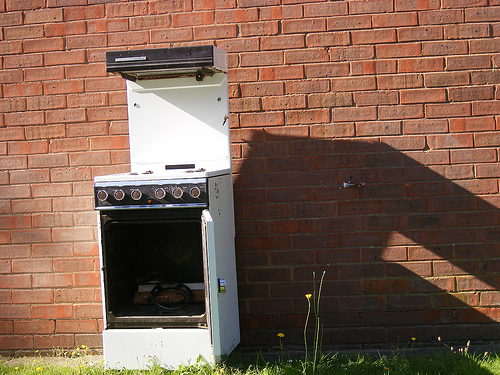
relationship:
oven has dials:
[93, 43, 246, 371] [89, 175, 215, 206]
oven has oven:
[93, 43, 246, 371] [93, 44, 245, 371]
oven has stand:
[93, 43, 246, 371] [107, 41, 231, 105]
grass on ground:
[3, 354, 499, 374] [3, 343, 497, 372]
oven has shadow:
[93, 43, 246, 371] [233, 122, 498, 348]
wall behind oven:
[2, 3, 495, 350] [93, 43, 246, 371]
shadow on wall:
[233, 122, 498, 348] [2, 3, 495, 350]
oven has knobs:
[93, 43, 246, 371] [89, 175, 215, 206]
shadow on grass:
[233, 122, 498, 348] [3, 354, 499, 374]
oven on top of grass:
[93, 43, 246, 371] [3, 354, 499, 374]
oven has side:
[93, 43, 246, 371] [203, 173, 247, 359]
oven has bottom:
[93, 43, 246, 371] [101, 328, 241, 372]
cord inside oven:
[146, 277, 194, 313] [93, 43, 246, 371]